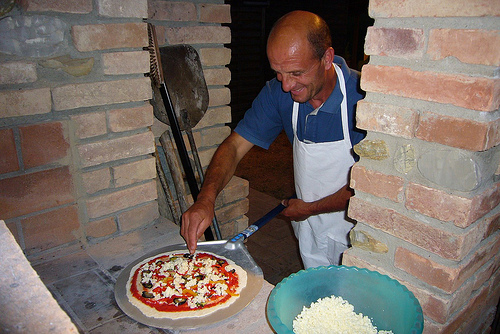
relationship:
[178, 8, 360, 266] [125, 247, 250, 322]
man making a pizza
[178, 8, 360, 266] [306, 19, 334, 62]
man has hair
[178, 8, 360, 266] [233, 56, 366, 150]
man has on a shirt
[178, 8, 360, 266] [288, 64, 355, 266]
man has on a apron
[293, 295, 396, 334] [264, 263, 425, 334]
cheese inside a bowl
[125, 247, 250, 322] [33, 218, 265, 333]
pizza on stone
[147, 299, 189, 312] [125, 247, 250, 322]
red tomato sauce on top of pizza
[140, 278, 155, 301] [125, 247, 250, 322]
black olives on top of pizza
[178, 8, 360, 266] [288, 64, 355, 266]
man wearing a white apron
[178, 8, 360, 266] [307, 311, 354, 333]
man applying cheese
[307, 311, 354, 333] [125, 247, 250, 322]
cheese to an uncooked pizza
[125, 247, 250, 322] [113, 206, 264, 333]
uncooked pizza sitting on top of a pizza peel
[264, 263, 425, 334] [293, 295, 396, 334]
bowl filled with cheese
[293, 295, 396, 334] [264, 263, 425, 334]
cheese sitting inside a bowl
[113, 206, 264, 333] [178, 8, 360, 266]
metal pizza peel held by a man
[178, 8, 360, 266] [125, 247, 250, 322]
man creating a pizza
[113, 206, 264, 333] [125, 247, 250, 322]
pizza peel with an pizza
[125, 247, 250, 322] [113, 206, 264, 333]
pizza sitting on top of a pizza peel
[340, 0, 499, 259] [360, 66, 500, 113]
post made of brick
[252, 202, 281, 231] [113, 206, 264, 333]
handle attached to a pizza peel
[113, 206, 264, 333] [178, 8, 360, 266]
pizza peel held by a man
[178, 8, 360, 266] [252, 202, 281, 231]
male pizza maker holding handle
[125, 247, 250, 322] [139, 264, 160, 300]
uncooked pizza with vegetable toppings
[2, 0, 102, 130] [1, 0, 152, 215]
part of a wall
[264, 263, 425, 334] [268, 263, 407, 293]
dish has an edge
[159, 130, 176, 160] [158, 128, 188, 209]
part of a stick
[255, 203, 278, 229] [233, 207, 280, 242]
part of a handle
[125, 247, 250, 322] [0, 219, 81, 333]
pizza ready for oven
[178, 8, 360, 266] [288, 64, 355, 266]
man wearing a apron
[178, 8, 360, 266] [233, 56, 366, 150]
man wearing a shirt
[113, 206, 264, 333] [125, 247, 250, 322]
spatula for taking out pizza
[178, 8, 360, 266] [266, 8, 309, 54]
man with no hair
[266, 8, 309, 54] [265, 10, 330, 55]
no hair on top of head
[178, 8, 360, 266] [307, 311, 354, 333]
man putting on cheese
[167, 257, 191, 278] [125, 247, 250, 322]
cheese on pizza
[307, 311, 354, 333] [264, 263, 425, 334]
cheese inside a bowl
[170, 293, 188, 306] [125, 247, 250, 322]
mushroom on top of pizza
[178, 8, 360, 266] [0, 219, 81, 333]
pizza chef putting pizza in oven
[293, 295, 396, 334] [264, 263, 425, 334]
cheese in a large bowl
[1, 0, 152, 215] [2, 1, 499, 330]
brick wall of pizzeria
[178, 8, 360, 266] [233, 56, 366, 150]
man wearing a polo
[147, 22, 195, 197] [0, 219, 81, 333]
baking tool for brick oven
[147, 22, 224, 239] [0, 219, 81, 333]
baking tool for brick oven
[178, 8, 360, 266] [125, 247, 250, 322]
man looking at pizza